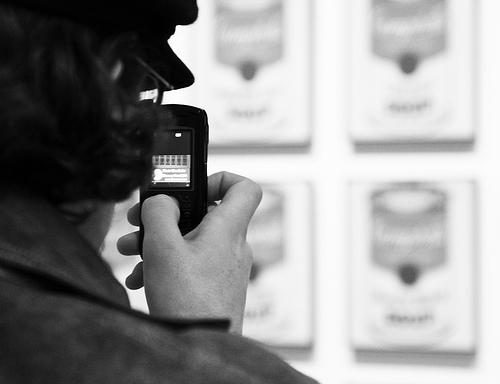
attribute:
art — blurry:
[203, 1, 482, 369]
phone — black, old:
[138, 97, 205, 264]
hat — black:
[1, 0, 202, 95]